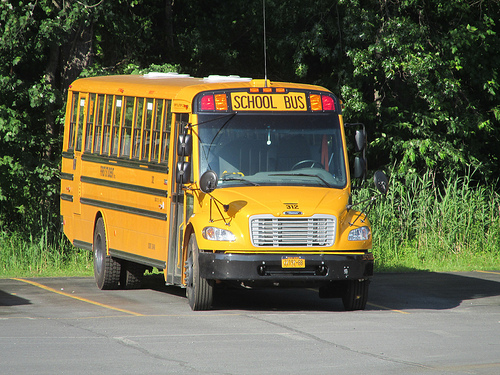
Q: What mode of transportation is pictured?
A: A school bus.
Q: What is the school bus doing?
A: It is parked.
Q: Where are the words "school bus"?
A: Above the windshield.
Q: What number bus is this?
A: 312.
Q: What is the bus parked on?
A: Cement.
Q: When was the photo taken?
A: During the daytime.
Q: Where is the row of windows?
A: On the bus's passenger side.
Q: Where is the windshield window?
A: On the front of the bus.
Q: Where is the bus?
A: On the road.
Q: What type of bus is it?
A: A yellow school bus.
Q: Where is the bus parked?
A: In a parking lot.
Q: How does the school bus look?
A: Vacant.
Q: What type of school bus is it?
A: Handicap accessible.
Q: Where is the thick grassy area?
A: Next to the bus.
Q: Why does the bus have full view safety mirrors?
A: For safety.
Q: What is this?
A: A bus.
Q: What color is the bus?
A: Yellow.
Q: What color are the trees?
A: Green.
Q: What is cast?
A: Shadow.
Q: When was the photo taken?
A: Daytime.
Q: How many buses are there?
A: One.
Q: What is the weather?
A: Sunny.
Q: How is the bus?
A: Parked.